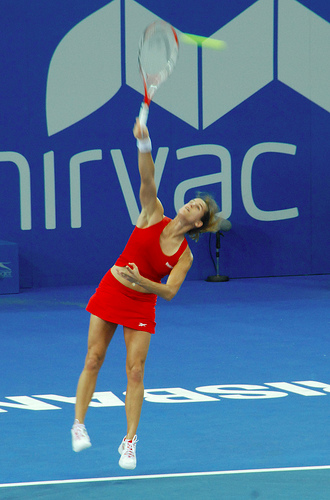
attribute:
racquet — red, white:
[135, 12, 183, 128]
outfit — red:
[74, 214, 186, 333]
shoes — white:
[67, 417, 150, 474]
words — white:
[1, 134, 313, 239]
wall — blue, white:
[8, 5, 328, 283]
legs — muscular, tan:
[74, 310, 154, 436]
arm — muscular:
[126, 120, 163, 211]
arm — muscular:
[168, 251, 196, 298]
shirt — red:
[121, 219, 185, 289]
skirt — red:
[88, 275, 160, 334]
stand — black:
[208, 228, 230, 287]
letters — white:
[5, 132, 312, 245]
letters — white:
[9, 380, 328, 412]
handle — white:
[135, 102, 150, 131]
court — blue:
[3, 279, 328, 499]